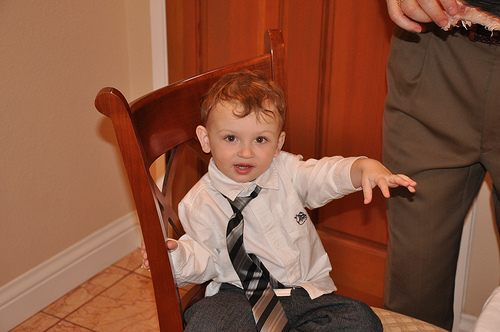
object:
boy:
[142, 69, 420, 330]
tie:
[219, 187, 287, 331]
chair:
[94, 29, 446, 332]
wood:
[117, 125, 177, 239]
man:
[383, 2, 500, 331]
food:
[439, 0, 500, 33]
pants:
[384, 28, 497, 325]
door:
[164, 0, 396, 307]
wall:
[1, 0, 92, 233]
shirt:
[167, 151, 362, 300]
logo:
[293, 211, 308, 226]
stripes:
[251, 282, 272, 314]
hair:
[201, 67, 284, 132]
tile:
[0, 240, 96, 331]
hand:
[360, 159, 415, 206]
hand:
[386, 0, 460, 33]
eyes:
[251, 135, 270, 145]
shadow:
[388, 186, 417, 202]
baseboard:
[1, 212, 147, 331]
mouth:
[232, 162, 256, 175]